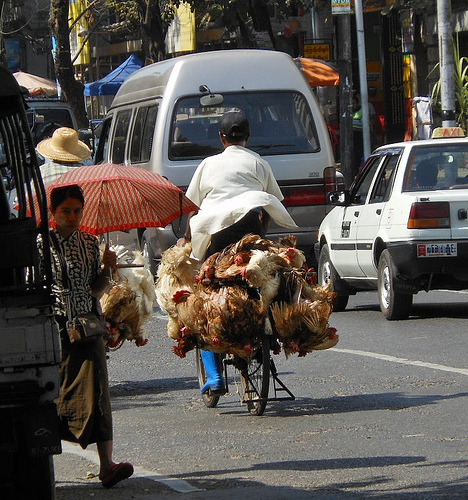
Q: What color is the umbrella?
A: Orange and white.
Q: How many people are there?
A: 3.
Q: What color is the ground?
A: Gray.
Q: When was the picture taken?
A: In the daytime.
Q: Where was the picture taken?
A: On a busy street.